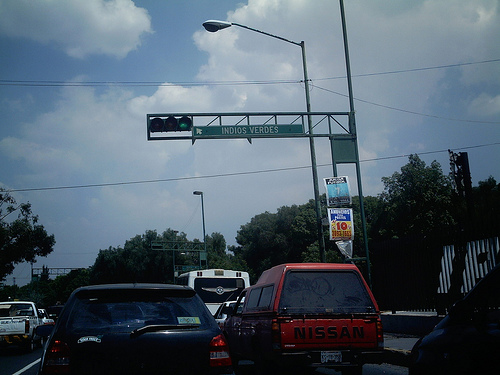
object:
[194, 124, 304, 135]
street sign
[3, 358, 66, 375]
street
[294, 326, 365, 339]
logo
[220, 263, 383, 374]
car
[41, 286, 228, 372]
car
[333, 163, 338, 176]
pole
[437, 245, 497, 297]
lettering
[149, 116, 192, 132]
traffic light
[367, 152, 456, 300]
tree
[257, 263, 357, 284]
canopy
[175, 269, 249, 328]
bus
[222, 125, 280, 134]
lettering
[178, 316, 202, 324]
sticker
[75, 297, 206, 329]
window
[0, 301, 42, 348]
truck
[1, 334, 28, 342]
bumper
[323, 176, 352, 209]
advertisement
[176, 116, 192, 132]
light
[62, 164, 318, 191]
power line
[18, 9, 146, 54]
cloud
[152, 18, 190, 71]
sky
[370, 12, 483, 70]
cloud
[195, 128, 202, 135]
arrow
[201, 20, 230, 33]
light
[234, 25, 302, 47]
pole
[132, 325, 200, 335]
wiper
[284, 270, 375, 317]
window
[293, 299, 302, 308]
dust